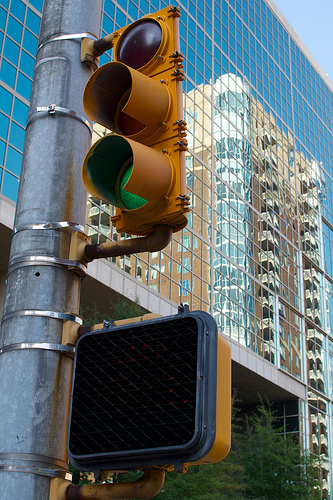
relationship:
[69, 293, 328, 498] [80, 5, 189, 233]
tree behind traffic light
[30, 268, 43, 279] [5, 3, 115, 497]
hole in pole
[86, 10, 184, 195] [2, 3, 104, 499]
light on pole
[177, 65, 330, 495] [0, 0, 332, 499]
reflection of another building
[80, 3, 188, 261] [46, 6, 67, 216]
traffic light on grey pole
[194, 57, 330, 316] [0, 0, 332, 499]
windows on building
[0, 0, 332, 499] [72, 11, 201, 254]
building on side of signal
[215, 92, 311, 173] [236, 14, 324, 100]
reflection of building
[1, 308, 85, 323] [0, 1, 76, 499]
clip on pole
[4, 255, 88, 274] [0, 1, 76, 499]
clip on pole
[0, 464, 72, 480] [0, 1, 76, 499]
clip on pole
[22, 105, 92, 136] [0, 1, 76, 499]
clip on pole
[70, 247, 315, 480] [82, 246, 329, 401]
building has concrete face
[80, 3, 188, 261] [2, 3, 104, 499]
traffic light on pole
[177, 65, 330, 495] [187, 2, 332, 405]
reflection on building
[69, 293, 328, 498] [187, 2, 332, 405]
tree near building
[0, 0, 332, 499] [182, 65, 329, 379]
building has reflection